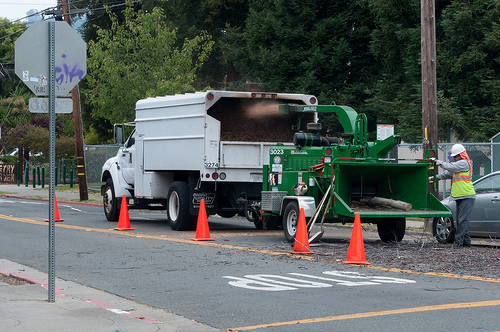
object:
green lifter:
[244, 99, 451, 241]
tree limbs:
[344, 175, 418, 210]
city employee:
[428, 144, 476, 248]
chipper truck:
[249, 101, 453, 247]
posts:
[17, 160, 44, 189]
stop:
[222, 270, 417, 292]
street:
[1, 195, 499, 331]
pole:
[69, 84, 89, 201]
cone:
[341, 212, 370, 264]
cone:
[289, 207, 313, 254]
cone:
[113, 194, 136, 231]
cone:
[44, 191, 64, 222]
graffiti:
[54, 53, 85, 85]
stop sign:
[14, 19, 87, 113]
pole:
[418, 0, 440, 234]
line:
[229, 299, 500, 332]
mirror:
[112, 122, 127, 149]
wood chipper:
[248, 100, 455, 244]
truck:
[99, 90, 321, 231]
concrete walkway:
[29, 278, 122, 329]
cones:
[45, 190, 370, 264]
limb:
[360, 196, 412, 211]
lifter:
[323, 148, 452, 218]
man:
[429, 143, 477, 248]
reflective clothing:
[429, 158, 476, 200]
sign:
[14, 21, 86, 96]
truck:
[250, 102, 452, 243]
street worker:
[428, 143, 476, 249]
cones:
[191, 199, 371, 267]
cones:
[291, 207, 372, 265]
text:
[221, 271, 415, 292]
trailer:
[251, 102, 453, 245]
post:
[41, 167, 45, 188]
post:
[24, 166, 29, 187]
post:
[32, 167, 36, 188]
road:
[5, 192, 499, 332]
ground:
[17, 187, 477, 314]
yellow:
[450, 170, 476, 198]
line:
[0, 211, 372, 267]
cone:
[191, 198, 215, 240]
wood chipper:
[258, 100, 455, 242]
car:
[430, 170, 499, 244]